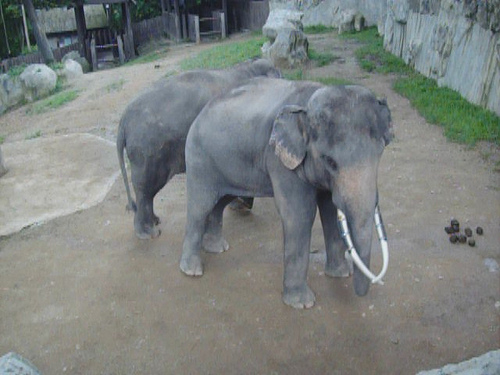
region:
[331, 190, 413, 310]
white elephant tusks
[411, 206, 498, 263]
pile of brown elephant poop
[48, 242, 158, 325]
dirt on the ground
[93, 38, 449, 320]
two elephants standing together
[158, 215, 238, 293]
elephants back feet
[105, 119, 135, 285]
tail of an elephant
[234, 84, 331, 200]
an elephant ear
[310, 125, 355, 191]
an elephants eye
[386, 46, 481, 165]
patch of green grass on the ground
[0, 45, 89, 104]
rock in the pen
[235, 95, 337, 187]
gray and pink elephant ear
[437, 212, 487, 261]
pile of elephant poop on the ground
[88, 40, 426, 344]
two elephants in a pen together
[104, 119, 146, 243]
a gray elephant tail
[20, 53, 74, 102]
rocks in the elephant exhibit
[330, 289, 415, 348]
leaves on the ground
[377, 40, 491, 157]
patch of green grass by the rocks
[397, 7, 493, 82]
a rocky wall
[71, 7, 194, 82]
wooden fence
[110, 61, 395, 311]
Two elephants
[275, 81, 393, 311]
Elephant with long tusks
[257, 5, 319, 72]
Large grey rock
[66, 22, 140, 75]
Brown Wooden gate of logs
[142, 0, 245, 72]
Gate to an animal enclosure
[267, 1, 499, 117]
Rock wall with green grass at bottom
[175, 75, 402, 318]
Large Elephant with metal braces on tusks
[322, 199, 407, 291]
Elephant tusks with grey metal braces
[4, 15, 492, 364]
Two elephants in a small enclosure in a zoo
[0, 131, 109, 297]
Brown cracked dry earth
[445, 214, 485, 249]
eight big elephant droppings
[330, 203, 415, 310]
Elephant tusks that are meeting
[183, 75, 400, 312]
A small elephant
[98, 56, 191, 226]
Another small elephant behind the first one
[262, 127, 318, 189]
dirt on the right ear of the elephant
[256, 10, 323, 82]
Big rock behind the elephants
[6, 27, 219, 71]
fence behind the elephants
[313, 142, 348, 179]
eyes are open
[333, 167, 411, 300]
dirt on elephant's trunk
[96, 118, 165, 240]
elephant tail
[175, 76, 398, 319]
grey and brown elephant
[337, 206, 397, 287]
long pointed tusks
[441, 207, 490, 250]
elephant droppings on ground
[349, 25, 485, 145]
green grass growing along side of wall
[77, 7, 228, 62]
wooden fence and gate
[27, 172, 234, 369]
dirt floor of elephant pen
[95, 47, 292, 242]
one elephant standing next to the other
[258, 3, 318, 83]
large grey boulder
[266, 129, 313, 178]
mud on elephant's ear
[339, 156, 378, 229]
mud on elephant's snout